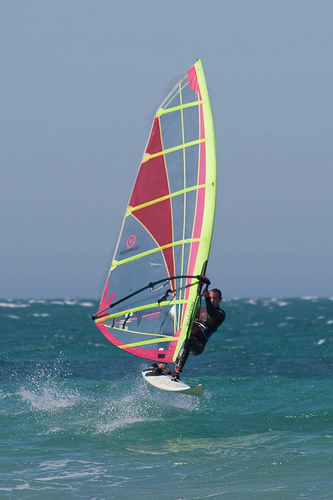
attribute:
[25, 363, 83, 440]
water — clear, splashing, blue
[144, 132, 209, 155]
strip — yellow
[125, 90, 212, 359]
sail — yellow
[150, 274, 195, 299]
handle — long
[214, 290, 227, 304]
hair — short, dark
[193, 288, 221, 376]
man — standing, windsurfing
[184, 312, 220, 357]
wet suit — dark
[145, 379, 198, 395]
board — white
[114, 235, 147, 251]
target — red